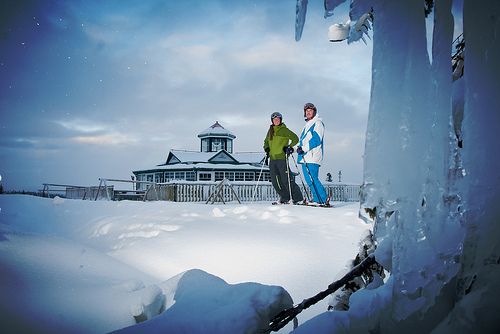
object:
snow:
[0, 192, 384, 333]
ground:
[0, 191, 394, 333]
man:
[295, 101, 332, 206]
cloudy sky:
[1, 0, 371, 193]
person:
[261, 112, 309, 206]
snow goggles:
[270, 112, 283, 119]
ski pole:
[292, 146, 315, 203]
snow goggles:
[304, 102, 316, 109]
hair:
[303, 102, 316, 118]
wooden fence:
[145, 177, 362, 204]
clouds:
[0, 0, 373, 190]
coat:
[261, 121, 299, 163]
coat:
[297, 116, 327, 169]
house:
[130, 120, 282, 202]